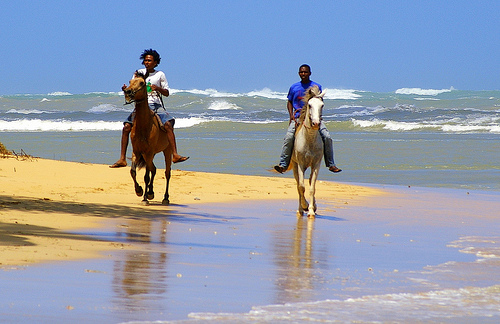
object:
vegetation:
[0, 142, 29, 162]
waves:
[3, 83, 498, 133]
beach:
[1, 139, 500, 320]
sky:
[0, 0, 497, 92]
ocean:
[1, 85, 500, 188]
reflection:
[289, 208, 315, 280]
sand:
[4, 151, 500, 321]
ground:
[371, 122, 397, 154]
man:
[275, 63, 341, 173]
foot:
[109, 159, 127, 167]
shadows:
[1, 191, 255, 258]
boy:
[108, 48, 191, 167]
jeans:
[123, 102, 174, 126]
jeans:
[278, 118, 337, 166]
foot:
[171, 156, 189, 164]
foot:
[274, 164, 285, 174]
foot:
[329, 166, 342, 173]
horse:
[288, 86, 328, 218]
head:
[305, 85, 325, 129]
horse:
[121, 81, 175, 205]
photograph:
[0, 0, 499, 324]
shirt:
[133, 63, 171, 105]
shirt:
[288, 80, 325, 119]